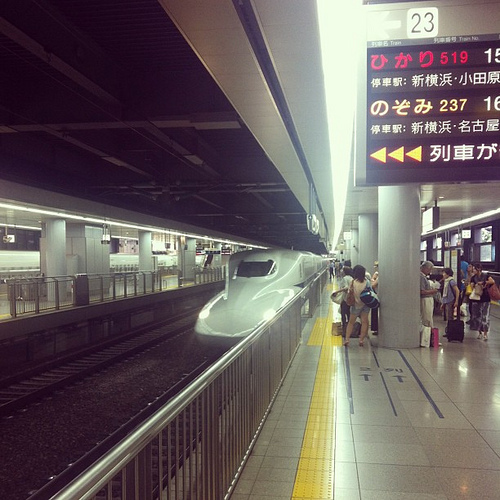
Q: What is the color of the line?
A: Yellow.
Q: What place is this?
A: Railway Station.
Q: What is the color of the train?
A: White.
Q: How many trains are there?
A: One.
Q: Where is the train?
A: In tracks.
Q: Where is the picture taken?
A: At a subway station.